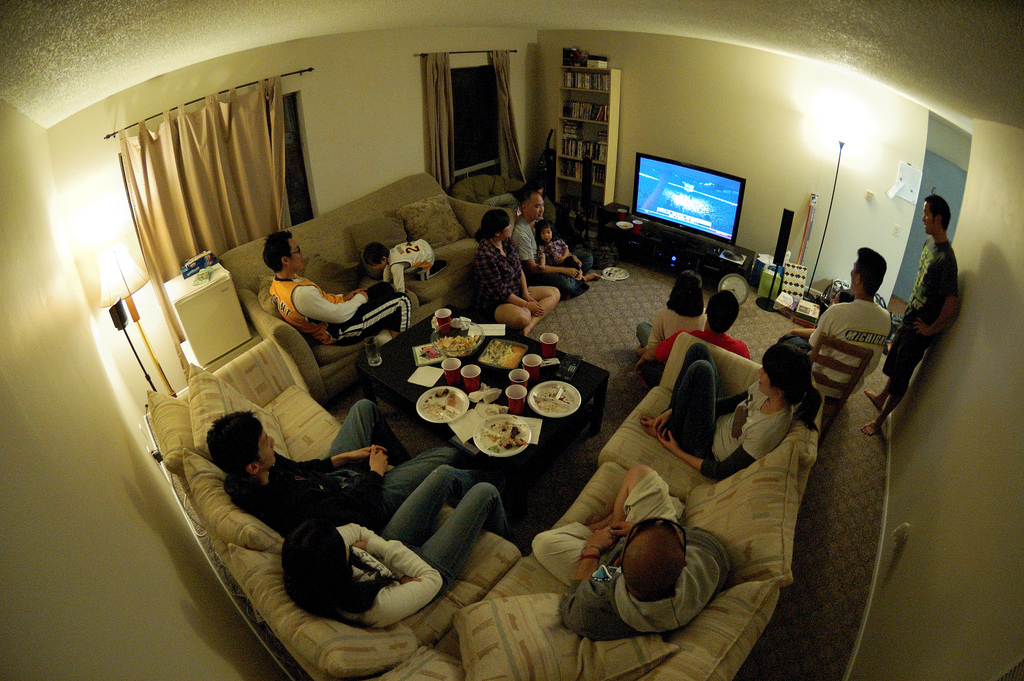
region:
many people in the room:
[106, 105, 999, 631]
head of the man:
[582, 491, 713, 625]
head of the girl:
[236, 475, 405, 640]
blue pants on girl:
[375, 452, 519, 561]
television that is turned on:
[604, 159, 794, 242]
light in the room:
[57, 183, 190, 403]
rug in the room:
[544, 262, 653, 365]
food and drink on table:
[302, 241, 660, 507]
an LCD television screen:
[625, 141, 765, 293]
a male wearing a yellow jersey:
[253, 225, 370, 350]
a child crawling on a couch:
[364, 228, 445, 308]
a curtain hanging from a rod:
[103, 82, 353, 261]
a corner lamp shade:
[73, 234, 206, 428]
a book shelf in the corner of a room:
[531, 54, 629, 251]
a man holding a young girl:
[512, 189, 593, 314]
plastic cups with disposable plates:
[413, 316, 601, 465]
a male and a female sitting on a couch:
[204, 377, 522, 638]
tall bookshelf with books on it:
[561, 54, 618, 201]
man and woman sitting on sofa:
[176, 407, 481, 627]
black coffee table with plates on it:
[363, 347, 597, 461]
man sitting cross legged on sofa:
[515, 462, 734, 631]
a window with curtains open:
[413, 50, 538, 188]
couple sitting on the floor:
[641, 268, 756, 360]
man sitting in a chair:
[786, 247, 930, 393]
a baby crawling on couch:
[352, 237, 463, 292]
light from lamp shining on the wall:
[796, 83, 904, 181]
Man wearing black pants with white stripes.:
[257, 222, 416, 349]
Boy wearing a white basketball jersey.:
[354, 236, 450, 294]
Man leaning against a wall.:
[857, 177, 968, 452]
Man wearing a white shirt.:
[781, 247, 896, 413]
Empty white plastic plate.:
[522, 377, 584, 417]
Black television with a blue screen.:
[624, 149, 748, 247]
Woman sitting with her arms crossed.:
[273, 459, 511, 634]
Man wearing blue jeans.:
[198, 395, 458, 535]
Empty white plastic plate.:
[411, 380, 472, 425]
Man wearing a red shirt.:
[640, 288, 755, 366]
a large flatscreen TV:
[632, 146, 747, 244]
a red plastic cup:
[460, 361, 483, 391]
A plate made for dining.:
[413, 383, 470, 426]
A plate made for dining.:
[473, 413, 532, 456]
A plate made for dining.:
[528, 378, 583, 418]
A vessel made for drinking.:
[441, 355, 462, 385]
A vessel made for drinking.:
[460, 361, 481, 396]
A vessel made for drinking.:
[503, 384, 529, 416]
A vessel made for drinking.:
[508, 367, 531, 393]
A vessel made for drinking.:
[521, 352, 542, 384]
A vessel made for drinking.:
[539, 333, 560, 360]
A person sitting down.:
[264, 228, 416, 347]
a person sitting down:
[675, 294, 821, 472]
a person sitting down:
[807, 253, 909, 375]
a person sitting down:
[889, 195, 976, 373]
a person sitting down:
[672, 285, 748, 378]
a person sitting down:
[655, 279, 742, 378]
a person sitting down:
[438, 177, 566, 358]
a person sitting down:
[333, 519, 414, 586]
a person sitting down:
[178, 361, 341, 521]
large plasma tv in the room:
[627, 144, 746, 234]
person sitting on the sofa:
[637, 332, 814, 469]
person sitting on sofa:
[514, 466, 737, 645]